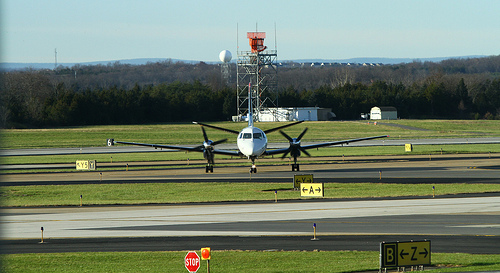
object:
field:
[0, 119, 499, 272]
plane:
[116, 99, 387, 173]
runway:
[0, 136, 499, 255]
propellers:
[276, 126, 311, 160]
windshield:
[251, 132, 263, 140]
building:
[344, 62, 356, 67]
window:
[241, 132, 249, 139]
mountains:
[0, 54, 499, 68]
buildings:
[373, 62, 384, 67]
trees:
[449, 78, 475, 121]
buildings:
[252, 99, 325, 123]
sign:
[299, 182, 325, 196]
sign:
[378, 237, 433, 268]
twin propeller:
[183, 125, 311, 165]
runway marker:
[75, 194, 86, 208]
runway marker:
[307, 222, 322, 240]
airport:
[0, 22, 499, 272]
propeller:
[182, 125, 228, 165]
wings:
[261, 133, 388, 157]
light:
[35, 227, 49, 245]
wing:
[115, 139, 237, 157]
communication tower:
[234, 22, 278, 123]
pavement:
[0, 195, 499, 255]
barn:
[368, 106, 400, 121]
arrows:
[311, 187, 320, 194]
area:
[0, 0, 499, 272]